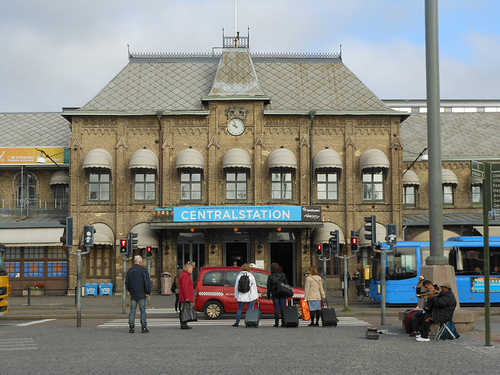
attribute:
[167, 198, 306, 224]
sign — central station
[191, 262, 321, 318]
van — red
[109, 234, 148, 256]
light — TRAFFIC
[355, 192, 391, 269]
light — TRAFFIC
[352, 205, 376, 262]
light — TRAFFIC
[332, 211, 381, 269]
light — TRAFFIC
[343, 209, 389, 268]
light — TRAFFIC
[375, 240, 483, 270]
bus — BLUE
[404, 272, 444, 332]
people — COUPLE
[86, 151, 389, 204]
windows — MANY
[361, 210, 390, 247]
light — TRAFFIC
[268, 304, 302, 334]
suitcase — BLACK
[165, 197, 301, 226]
sign — BLUE, WHITE, CENTRAL STATION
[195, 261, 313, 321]
car — red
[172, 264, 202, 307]
jacket — red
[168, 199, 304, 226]
sign — blue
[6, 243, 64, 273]
windows — colorful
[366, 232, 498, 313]
bus — blue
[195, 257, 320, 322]
car — red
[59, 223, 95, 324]
light post — changing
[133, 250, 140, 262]
hair — white